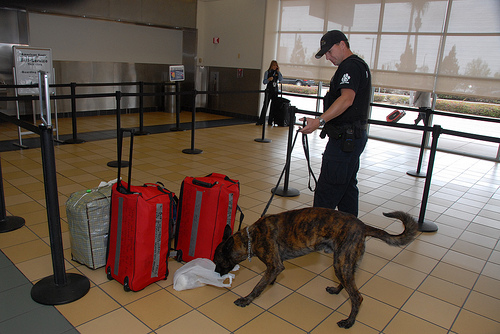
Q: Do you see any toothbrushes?
A: No, there are no toothbrushes.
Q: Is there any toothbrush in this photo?
A: No, there are no toothbrushes.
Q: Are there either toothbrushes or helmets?
A: No, there are no toothbrushes or helmets.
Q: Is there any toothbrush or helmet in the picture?
A: No, there are no toothbrushes or helmets.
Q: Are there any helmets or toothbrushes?
A: No, there are no toothbrushes or helmets.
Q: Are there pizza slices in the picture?
A: No, there are no pizza slices.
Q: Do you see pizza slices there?
A: No, there are no pizza slices.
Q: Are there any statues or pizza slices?
A: No, there are no pizza slices or statues.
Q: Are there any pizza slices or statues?
A: No, there are no pizza slices or statues.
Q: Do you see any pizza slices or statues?
A: No, there are no pizza slices or statues.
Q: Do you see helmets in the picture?
A: No, there are no helmets.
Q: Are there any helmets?
A: No, there are no helmets.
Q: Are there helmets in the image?
A: No, there are no helmets.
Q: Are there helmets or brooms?
A: No, there are no helmets or brooms.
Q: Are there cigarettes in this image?
A: No, there are no cigarettes.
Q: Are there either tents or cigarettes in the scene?
A: No, there are no cigarettes or tents.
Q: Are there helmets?
A: No, there are no helmets.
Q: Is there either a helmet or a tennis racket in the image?
A: No, there are no helmets or rackets.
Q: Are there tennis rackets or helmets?
A: No, there are no helmets or tennis rackets.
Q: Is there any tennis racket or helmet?
A: No, there are no helmets or rackets.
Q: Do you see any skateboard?
A: No, there are no skateboards.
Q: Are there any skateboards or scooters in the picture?
A: No, there are no skateboards or scooters.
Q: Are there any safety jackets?
A: No, there are no safety jackets.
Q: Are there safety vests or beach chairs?
A: No, there are no safety vests or beach chairs.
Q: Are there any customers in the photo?
A: No, there are no customers.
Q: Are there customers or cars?
A: No, there are no customers or cars.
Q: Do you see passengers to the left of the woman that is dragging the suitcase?
A: Yes, there are passengers to the left of the woman.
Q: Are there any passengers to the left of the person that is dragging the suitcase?
A: Yes, there are passengers to the left of the woman.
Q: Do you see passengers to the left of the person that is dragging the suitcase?
A: Yes, there are passengers to the left of the woman.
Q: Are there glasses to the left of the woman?
A: No, there are passengers to the left of the woman.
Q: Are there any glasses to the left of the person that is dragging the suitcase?
A: No, there are passengers to the left of the woman.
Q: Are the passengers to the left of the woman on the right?
A: Yes, the passengers are to the left of the woman.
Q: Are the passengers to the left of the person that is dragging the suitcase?
A: Yes, the passengers are to the left of the woman.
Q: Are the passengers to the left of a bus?
A: No, the passengers are to the left of the woman.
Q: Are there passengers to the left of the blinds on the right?
A: Yes, there are passengers to the left of the blinds.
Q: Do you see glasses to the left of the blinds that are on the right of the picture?
A: No, there are passengers to the left of the blinds.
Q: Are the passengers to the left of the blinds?
A: Yes, the passengers are to the left of the blinds.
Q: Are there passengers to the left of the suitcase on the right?
A: Yes, there are passengers to the left of the suitcase.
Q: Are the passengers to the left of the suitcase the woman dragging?
A: Yes, the passengers are to the left of the suitcase.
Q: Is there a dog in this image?
A: Yes, there is a dog.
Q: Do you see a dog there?
A: Yes, there is a dog.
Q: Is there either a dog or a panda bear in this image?
A: Yes, there is a dog.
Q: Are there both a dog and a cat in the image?
A: No, there is a dog but no cats.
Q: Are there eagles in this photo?
A: No, there are no eagles.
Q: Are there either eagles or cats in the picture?
A: No, there are no eagles or cats.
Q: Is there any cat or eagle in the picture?
A: No, there are no eagles or cats.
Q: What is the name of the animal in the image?
A: The animal is a dog.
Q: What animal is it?
A: The animal is a dog.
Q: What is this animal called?
A: This is a dog.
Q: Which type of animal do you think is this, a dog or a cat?
A: This is a dog.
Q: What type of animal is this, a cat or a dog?
A: This is a dog.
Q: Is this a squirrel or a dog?
A: This is a dog.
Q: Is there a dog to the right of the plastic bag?
A: Yes, there is a dog to the right of the bag.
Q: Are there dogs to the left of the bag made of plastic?
A: No, the dog is to the right of the bag.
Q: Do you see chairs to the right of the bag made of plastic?
A: No, there is a dog to the right of the bag.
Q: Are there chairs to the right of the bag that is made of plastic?
A: No, there is a dog to the right of the bag.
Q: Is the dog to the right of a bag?
A: Yes, the dog is to the right of a bag.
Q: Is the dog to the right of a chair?
A: No, the dog is to the right of a bag.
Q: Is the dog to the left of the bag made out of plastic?
A: No, the dog is to the right of the bag.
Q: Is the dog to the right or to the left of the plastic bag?
A: The dog is to the right of the bag.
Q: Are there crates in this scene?
A: No, there are no crates.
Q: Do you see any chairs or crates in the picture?
A: No, there are no crates or chairs.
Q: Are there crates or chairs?
A: No, there are no crates or chairs.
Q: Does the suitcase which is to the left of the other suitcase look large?
A: Yes, the suitcase is large.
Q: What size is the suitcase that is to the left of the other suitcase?
A: The suitcase is large.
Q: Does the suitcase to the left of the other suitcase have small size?
A: No, the suitcase is large.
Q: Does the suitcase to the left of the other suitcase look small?
A: No, the suitcase is large.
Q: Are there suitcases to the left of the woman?
A: Yes, there is a suitcase to the left of the woman.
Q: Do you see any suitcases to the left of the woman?
A: Yes, there is a suitcase to the left of the woman.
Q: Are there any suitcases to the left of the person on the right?
A: Yes, there is a suitcase to the left of the woman.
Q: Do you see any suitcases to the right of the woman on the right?
A: No, the suitcase is to the left of the woman.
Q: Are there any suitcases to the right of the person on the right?
A: No, the suitcase is to the left of the woman.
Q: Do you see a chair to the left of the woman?
A: No, there is a suitcase to the left of the woman.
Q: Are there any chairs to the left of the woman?
A: No, there is a suitcase to the left of the woman.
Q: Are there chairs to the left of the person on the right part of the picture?
A: No, there is a suitcase to the left of the woman.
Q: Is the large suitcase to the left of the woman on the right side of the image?
A: Yes, the suitcase is to the left of the woman.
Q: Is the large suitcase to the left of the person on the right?
A: Yes, the suitcase is to the left of the woman.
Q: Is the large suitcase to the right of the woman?
A: No, the suitcase is to the left of the woman.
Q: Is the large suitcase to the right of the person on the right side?
A: No, the suitcase is to the left of the woman.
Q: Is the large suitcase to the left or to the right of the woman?
A: The suitcase is to the left of the woman.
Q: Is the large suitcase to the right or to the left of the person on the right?
A: The suitcase is to the left of the woman.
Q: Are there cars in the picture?
A: No, there are no cars.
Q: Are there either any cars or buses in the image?
A: No, there are no cars or buses.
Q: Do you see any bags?
A: Yes, there is a bag.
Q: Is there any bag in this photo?
A: Yes, there is a bag.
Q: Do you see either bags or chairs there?
A: Yes, there is a bag.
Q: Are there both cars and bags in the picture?
A: No, there is a bag but no cars.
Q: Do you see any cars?
A: No, there are no cars.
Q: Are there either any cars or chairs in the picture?
A: No, there are no cars or chairs.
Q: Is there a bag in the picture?
A: Yes, there is a bag.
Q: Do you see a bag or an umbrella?
A: Yes, there is a bag.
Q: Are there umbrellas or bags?
A: Yes, there is a bag.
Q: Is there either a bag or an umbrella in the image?
A: Yes, there is a bag.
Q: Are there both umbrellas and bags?
A: No, there is a bag but no umbrellas.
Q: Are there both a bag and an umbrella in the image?
A: No, there is a bag but no umbrellas.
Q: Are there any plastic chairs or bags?
A: Yes, there is a plastic bag.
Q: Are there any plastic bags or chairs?
A: Yes, there is a plastic bag.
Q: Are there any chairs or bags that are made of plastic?
A: Yes, the bag is made of plastic.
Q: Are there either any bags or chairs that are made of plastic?
A: Yes, the bag is made of plastic.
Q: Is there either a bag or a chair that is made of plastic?
A: Yes, the bag is made of plastic.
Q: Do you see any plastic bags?
A: Yes, there is a bag that is made of plastic.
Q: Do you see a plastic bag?
A: Yes, there is a bag that is made of plastic.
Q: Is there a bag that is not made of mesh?
A: Yes, there is a bag that is made of plastic.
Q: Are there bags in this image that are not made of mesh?
A: Yes, there is a bag that is made of plastic.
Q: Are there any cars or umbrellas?
A: No, there are no cars or umbrellas.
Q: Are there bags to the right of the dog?
A: No, the bag is to the left of the dog.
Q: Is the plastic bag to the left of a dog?
A: Yes, the bag is to the left of a dog.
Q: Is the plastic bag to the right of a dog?
A: No, the bag is to the left of a dog.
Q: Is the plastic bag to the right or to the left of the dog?
A: The bag is to the left of the dog.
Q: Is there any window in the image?
A: Yes, there is a window.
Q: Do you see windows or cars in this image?
A: Yes, there is a window.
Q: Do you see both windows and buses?
A: No, there is a window but no buses.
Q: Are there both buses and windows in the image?
A: No, there is a window but no buses.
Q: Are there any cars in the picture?
A: No, there are no cars.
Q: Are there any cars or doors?
A: No, there are no cars or doors.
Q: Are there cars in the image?
A: No, there are no cars.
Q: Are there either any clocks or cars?
A: No, there are no cars or clocks.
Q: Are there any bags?
A: Yes, there is a bag.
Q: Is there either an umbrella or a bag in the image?
A: Yes, there is a bag.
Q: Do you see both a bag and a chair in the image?
A: No, there is a bag but no chairs.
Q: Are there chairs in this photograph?
A: No, there are no chairs.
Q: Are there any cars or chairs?
A: No, there are no chairs or cars.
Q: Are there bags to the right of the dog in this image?
A: No, the bag is to the left of the dog.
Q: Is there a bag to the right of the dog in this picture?
A: No, the bag is to the left of the dog.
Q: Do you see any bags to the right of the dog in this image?
A: No, the bag is to the left of the dog.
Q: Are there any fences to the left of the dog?
A: No, there is a bag to the left of the dog.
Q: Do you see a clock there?
A: No, there are no clocks.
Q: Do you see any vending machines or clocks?
A: No, there are no clocks or vending machines.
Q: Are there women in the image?
A: Yes, there is a woman.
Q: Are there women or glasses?
A: Yes, there is a woman.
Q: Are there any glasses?
A: No, there are no glasses.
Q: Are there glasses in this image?
A: No, there are no glasses.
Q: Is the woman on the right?
A: Yes, the woman is on the right of the image.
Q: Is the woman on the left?
A: No, the woman is on the right of the image.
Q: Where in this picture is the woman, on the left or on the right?
A: The woman is on the right of the image.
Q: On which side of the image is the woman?
A: The woman is on the right of the image.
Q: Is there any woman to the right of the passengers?
A: Yes, there is a woman to the right of the passengers.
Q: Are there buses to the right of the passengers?
A: No, there is a woman to the right of the passengers.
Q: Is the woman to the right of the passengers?
A: Yes, the woman is to the right of the passengers.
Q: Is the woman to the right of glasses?
A: No, the woman is to the right of the passengers.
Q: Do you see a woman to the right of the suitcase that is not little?
A: Yes, there is a woman to the right of the suitcase.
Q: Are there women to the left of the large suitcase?
A: No, the woman is to the right of the suitcase.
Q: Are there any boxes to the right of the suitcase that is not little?
A: No, there is a woman to the right of the suitcase.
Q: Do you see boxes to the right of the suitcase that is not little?
A: No, there is a woman to the right of the suitcase.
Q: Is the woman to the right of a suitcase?
A: Yes, the woman is to the right of a suitcase.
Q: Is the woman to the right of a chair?
A: No, the woman is to the right of a suitcase.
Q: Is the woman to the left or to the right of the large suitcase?
A: The woman is to the right of the suitcase.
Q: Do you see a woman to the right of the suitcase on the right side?
A: Yes, there is a woman to the right of the suitcase.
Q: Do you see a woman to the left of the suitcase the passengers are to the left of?
A: No, the woman is to the right of the suitcase.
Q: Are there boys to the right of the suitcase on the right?
A: No, there is a woman to the right of the suitcase.